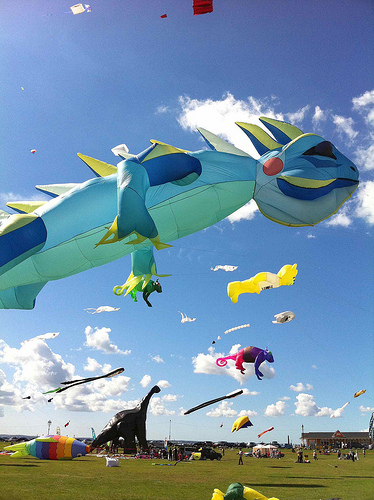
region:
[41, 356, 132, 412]
kite in the sky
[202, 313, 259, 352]
kite in the sky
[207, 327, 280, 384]
kite in the sky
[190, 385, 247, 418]
kite in the sky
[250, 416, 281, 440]
kite in the sky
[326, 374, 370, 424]
kite in the sky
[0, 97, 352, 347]
kite in the sky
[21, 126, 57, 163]
kite in the sky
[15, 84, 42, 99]
kite in the sky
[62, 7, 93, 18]
kite in the sky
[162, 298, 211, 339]
kite in the sky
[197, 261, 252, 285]
kite in the sky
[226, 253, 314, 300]
kite in the sky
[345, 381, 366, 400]
kite in the sky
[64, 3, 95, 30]
kite in the sky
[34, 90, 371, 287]
a dragon shaped kite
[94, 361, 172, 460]
a toy dinosaur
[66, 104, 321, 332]
a big balloon dragon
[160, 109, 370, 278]
the head of a balloon dragon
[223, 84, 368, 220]
the head of a balloon dragon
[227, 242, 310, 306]
This is a kite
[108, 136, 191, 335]
This is a kite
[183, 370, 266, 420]
This is a kite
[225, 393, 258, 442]
This is a kite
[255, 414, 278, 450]
This is a kite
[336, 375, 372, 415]
This is a kite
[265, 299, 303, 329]
This is a kite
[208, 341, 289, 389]
This is a kite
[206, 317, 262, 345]
This is a kite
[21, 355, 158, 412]
This is a kite